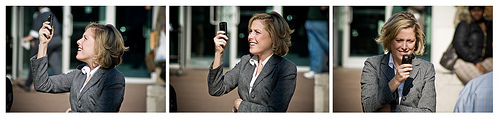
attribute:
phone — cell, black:
[46, 12, 53, 34]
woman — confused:
[208, 11, 300, 112]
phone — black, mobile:
[219, 21, 227, 30]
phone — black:
[401, 52, 411, 64]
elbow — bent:
[33, 74, 56, 95]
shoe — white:
[303, 69, 316, 79]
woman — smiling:
[359, 10, 440, 112]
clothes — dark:
[31, 12, 62, 83]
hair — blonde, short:
[85, 20, 130, 70]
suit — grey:
[30, 56, 127, 112]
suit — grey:
[207, 55, 297, 114]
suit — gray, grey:
[361, 57, 436, 112]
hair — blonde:
[246, 11, 296, 57]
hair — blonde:
[375, 11, 425, 59]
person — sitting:
[451, 5, 496, 82]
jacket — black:
[454, 17, 493, 60]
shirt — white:
[81, 66, 100, 92]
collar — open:
[248, 55, 274, 65]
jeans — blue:
[306, 21, 331, 73]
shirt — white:
[247, 55, 274, 94]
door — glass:
[63, 6, 117, 73]